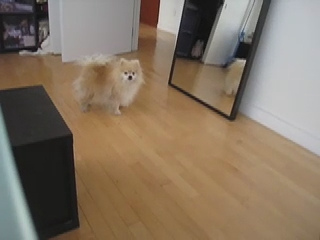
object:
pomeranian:
[69, 54, 146, 116]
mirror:
[166, 0, 269, 122]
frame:
[166, 0, 269, 121]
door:
[58, 0, 141, 64]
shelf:
[0, 0, 52, 54]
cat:
[190, 38, 205, 61]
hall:
[138, 0, 184, 51]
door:
[138, 0, 161, 27]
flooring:
[0, 23, 320, 240]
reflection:
[221, 57, 249, 97]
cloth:
[18, 31, 63, 57]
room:
[0, 0, 320, 239]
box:
[0, 85, 79, 240]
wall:
[174, 0, 320, 158]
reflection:
[169, 0, 225, 61]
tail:
[74, 50, 108, 99]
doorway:
[63, 25, 182, 84]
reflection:
[199, 0, 250, 68]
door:
[198, 0, 249, 68]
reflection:
[168, 56, 265, 118]